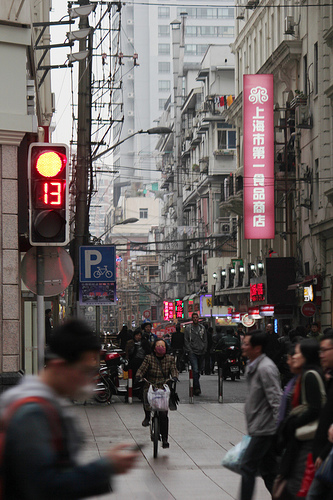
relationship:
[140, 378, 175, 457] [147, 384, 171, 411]
bike has bag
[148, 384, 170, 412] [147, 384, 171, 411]
bag in bag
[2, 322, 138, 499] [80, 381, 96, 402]
guy wearing mask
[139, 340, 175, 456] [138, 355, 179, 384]
man wearing jacket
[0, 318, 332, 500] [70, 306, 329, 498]
people on street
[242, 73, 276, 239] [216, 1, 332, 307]
sign on building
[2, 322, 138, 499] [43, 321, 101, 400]
guy has head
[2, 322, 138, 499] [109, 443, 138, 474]
guy has hand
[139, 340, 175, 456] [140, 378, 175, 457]
man riding bike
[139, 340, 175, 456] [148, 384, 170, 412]
man has bag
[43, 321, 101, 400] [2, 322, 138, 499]
head of guy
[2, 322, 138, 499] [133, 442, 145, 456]
guy holding phone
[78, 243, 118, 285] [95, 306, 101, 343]
sign on pole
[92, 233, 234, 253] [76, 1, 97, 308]
wires on pole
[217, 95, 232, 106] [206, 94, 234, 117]
clothes on balcony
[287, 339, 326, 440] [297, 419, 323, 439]
woman holding purse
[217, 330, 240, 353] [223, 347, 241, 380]
man riding motorcycle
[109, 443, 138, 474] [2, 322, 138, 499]
hand of guy